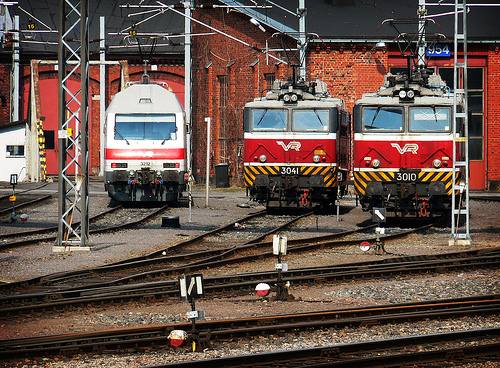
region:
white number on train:
[279, 165, 286, 175]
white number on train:
[291, 165, 296, 176]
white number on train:
[294, 165, 299, 176]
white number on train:
[396, 170, 403, 182]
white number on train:
[401, 172, 408, 182]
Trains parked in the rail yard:
[101, 55, 492, 229]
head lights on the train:
[259, 149, 328, 166]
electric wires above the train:
[90, 3, 212, 57]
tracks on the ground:
[238, 200, 384, 273]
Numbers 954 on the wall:
[418, 40, 452, 65]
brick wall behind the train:
[318, 55, 379, 94]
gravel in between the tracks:
[318, 278, 424, 306]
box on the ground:
[155, 208, 182, 232]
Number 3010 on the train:
[389, 165, 422, 185]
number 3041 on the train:
[276, 161, 301, 179]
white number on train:
[396, 172, 404, 182]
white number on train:
[407, 170, 411, 180]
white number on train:
[409, 173, 421, 183]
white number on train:
[280, 166, 286, 176]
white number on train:
[285, 165, 291, 175]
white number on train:
[290, 165, 297, 175]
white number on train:
[295, 166, 300, 178]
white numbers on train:
[395, 173, 417, 182]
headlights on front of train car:
[259, 153, 321, 163]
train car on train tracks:
[1, 207, 315, 319]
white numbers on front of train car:
[279, 165, 298, 175]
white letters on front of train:
[275, 139, 300, 152]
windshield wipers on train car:
[257, 108, 324, 125]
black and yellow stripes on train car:
[352, 168, 459, 197]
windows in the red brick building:
[389, 65, 484, 160]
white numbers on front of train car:
[395, 170, 417, 182]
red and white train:
[102, 81, 185, 205]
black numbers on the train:
[138, 160, 149, 167]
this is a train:
[216, 40, 351, 243]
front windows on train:
[228, 83, 329, 139]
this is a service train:
[68, 19, 206, 214]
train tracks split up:
[75, 195, 392, 315]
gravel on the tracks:
[212, 245, 470, 364]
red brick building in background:
[191, 0, 498, 184]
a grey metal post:
[33, 0, 122, 257]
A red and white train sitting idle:
[102, 84, 187, 208]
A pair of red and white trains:
[241, 73, 465, 224]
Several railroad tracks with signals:
[14, 227, 498, 357]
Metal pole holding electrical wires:
[53, 2, 95, 256]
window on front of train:
[115, 111, 145, 138]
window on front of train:
[145, 114, 175, 139]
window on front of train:
[251, 108, 289, 130]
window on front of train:
[291, 108, 328, 130]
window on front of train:
[363, 107, 403, 130]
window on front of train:
[408, 107, 451, 132]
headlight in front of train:
[258, 158, 268, 161]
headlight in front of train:
[312, 154, 319, 162]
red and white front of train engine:
[240, 99, 344, 165]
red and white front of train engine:
[352, 99, 459, 172]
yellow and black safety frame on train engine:
[242, 160, 335, 190]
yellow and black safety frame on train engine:
[353, 168, 463, 199]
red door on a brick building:
[21, 69, 90, 180]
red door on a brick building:
[116, 69, 183, 110]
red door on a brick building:
[385, 49, 489, 191]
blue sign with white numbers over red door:
[424, 42, 451, 59]